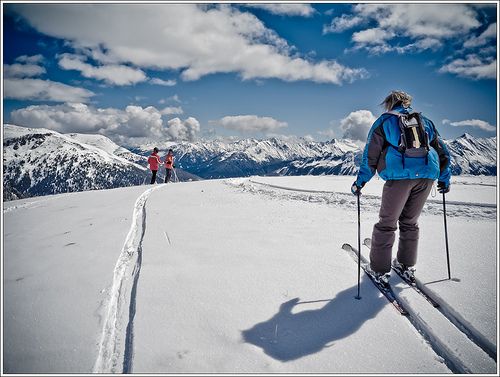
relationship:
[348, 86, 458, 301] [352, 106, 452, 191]
person wearing jacket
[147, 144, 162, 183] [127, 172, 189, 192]
person on skis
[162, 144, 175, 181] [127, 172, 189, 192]
person on skis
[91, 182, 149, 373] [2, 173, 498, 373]
long tracks in snow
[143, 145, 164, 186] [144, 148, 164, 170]
person wearing jacket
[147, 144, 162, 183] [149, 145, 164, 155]
person wearing hat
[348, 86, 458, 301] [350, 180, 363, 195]
person wearing gloves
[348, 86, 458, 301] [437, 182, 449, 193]
person wearing gloves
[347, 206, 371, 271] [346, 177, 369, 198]
ski pole in skier's hand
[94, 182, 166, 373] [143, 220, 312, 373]
long tracks in snow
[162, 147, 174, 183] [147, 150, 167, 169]
skier in jacket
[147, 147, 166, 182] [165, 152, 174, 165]
skiers in jacket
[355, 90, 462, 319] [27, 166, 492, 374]
skier going down mountain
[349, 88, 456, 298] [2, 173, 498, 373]
woman skiing on snow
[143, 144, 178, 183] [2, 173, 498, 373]
people standing on snow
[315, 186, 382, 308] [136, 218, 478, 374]
pole sticking in ground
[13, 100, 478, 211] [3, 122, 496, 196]
range covered in snow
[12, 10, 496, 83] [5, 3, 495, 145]
white clouds in sky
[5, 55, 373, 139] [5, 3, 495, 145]
white clouds in sky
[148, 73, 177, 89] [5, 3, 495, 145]
cloud in sky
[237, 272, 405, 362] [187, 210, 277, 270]
shadow in snow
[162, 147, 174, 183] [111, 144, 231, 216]
skier on hill